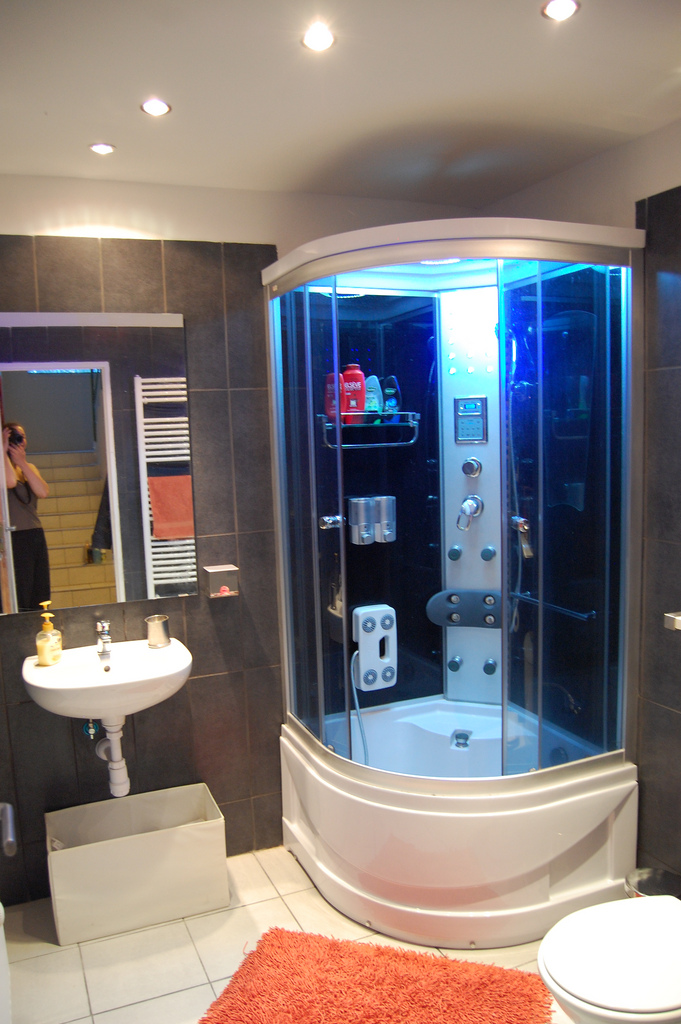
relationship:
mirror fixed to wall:
[25, 380, 106, 549] [110, 238, 218, 299]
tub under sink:
[29, 797, 213, 913] [40, 633, 186, 706]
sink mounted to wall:
[17, 627, 202, 805] [6, 233, 298, 915]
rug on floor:
[185, 921, 552, 1023] [5, 846, 532, 1015]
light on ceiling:
[144, 92, 170, 121] [3, 3, 679, 217]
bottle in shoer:
[339, 359, 368, 427] [243, 211, 651, 953]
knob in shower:
[459, 456, 483, 480] [248, 217, 651, 952]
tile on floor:
[72, 913, 213, 1015] [5, 846, 532, 1015]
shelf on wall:
[315, 408, 419, 456] [276, 278, 455, 729]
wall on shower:
[276, 278, 455, 729] [248, 217, 651, 952]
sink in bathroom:
[18, 618, 194, 798] [3, 7, 679, 1021]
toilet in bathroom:
[533, 884, 679, 1023] [3, 7, 679, 1021]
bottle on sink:
[34, 597, 63, 670] [17, 627, 202, 805]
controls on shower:
[452, 393, 496, 452] [248, 217, 651, 952]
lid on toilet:
[541, 891, 681, 1015] [540, 872, 678, 1023]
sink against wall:
[17, 627, 202, 805] [1, 173, 499, 924]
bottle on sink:
[29, 609, 62, 667] [17, 627, 202, 805]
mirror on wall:
[0, 364, 119, 612] [1, 173, 499, 924]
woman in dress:
[5, 422, 57, 615] [3, 464, 58, 612]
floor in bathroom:
[5, 846, 532, 1015] [3, 7, 679, 1021]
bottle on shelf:
[342, 362, 365, 424] [315, 408, 427, 463]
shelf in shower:
[315, 408, 427, 463] [248, 217, 651, 952]